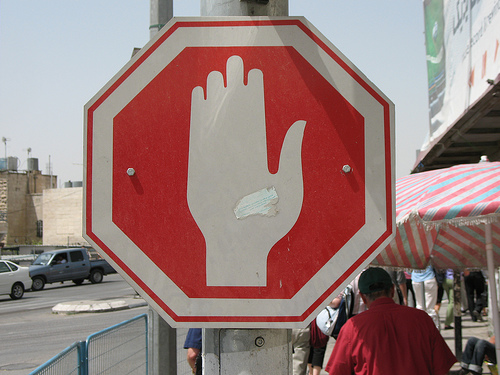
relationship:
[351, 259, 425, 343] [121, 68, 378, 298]
man near sign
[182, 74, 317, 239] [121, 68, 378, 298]
hand on sign